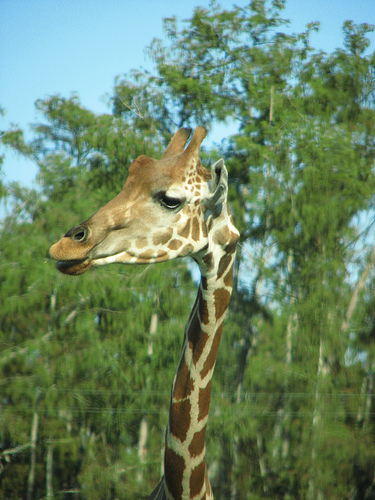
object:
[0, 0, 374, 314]
clouds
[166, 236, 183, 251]
spot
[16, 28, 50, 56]
white clouds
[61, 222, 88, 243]
nose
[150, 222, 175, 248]
giraffe pattern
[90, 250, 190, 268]
jaw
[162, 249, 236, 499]
neck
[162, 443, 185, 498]
spot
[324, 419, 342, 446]
leaves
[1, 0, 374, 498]
tree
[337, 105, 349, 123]
leaf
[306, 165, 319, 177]
leaf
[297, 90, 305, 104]
leaf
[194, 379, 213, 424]
spot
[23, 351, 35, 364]
leaf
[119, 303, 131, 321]
leaf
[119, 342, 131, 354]
leaf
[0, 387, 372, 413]
fence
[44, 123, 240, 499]
giraffe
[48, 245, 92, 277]
mouth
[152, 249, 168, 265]
spot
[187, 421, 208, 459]
spot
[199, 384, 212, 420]
brown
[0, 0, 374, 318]
sky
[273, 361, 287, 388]
leaves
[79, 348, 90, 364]
leaves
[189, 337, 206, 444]
skin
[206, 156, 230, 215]
ear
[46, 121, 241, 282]
head